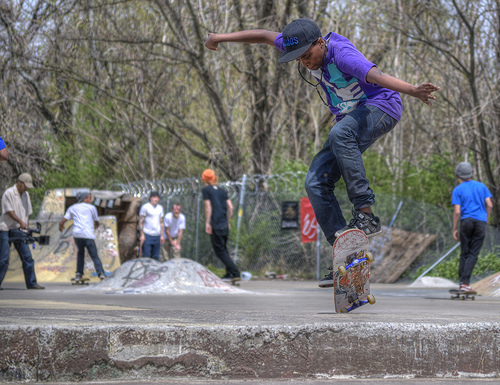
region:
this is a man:
[227, 1, 412, 259]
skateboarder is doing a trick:
[200, 13, 462, 369]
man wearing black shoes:
[329, 188, 388, 239]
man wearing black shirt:
[194, 177, 237, 236]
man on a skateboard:
[182, 13, 474, 313]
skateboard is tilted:
[324, 231, 386, 314]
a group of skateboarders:
[3, 5, 498, 317]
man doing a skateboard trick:
[194, 16, 452, 316]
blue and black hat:
[273, 15, 323, 60]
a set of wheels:
[331, 250, 378, 273]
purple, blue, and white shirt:
[268, 25, 425, 124]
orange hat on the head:
[198, 165, 222, 182]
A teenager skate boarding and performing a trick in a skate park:
[202, 17, 437, 287]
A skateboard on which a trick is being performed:
[330, 227, 370, 312]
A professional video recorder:
[5, 221, 48, 242]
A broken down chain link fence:
[116, 170, 498, 285]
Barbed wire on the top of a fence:
[121, 179, 306, 191]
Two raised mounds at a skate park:
[88, 257, 238, 290]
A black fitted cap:
[276, 18, 321, 65]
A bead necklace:
[297, 59, 327, 109]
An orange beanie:
[202, 170, 215, 183]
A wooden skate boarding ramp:
[3, 217, 122, 282]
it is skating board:
[328, 221, 378, 321]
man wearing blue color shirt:
[449, 179, 497, 219]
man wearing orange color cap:
[197, 168, 254, 278]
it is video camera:
[8, 220, 49, 251]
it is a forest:
[8, 5, 250, 168]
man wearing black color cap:
[274, 18, 441, 213]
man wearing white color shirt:
[68, 189, 110, 242]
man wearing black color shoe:
[337, 211, 389, 243]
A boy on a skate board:
[206, 15, 438, 314]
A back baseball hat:
[279, 18, 321, 63]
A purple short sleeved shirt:
[275, 31, 402, 121]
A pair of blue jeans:
[305, 103, 397, 245]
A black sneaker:
[334, 208, 381, 240]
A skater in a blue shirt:
[446, 161, 494, 302]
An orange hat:
[200, 167, 217, 184]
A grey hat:
[453, 161, 474, 180]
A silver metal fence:
[104, 171, 499, 283]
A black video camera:
[10, 221, 50, 248]